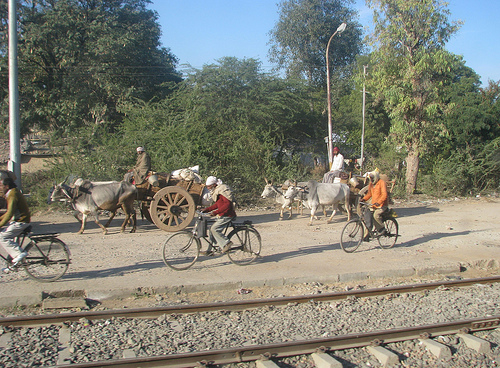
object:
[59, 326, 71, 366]
board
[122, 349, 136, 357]
board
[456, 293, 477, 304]
board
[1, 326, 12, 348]
board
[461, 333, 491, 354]
board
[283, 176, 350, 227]
ox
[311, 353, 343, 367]
board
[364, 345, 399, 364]
wooden board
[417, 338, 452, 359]
board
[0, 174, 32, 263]
man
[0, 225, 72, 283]
bicycle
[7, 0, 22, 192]
pole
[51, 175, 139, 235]
ox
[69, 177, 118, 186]
ox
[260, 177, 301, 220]
ox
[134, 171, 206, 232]
cart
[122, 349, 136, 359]
board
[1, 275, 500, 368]
tracks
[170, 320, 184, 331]
board